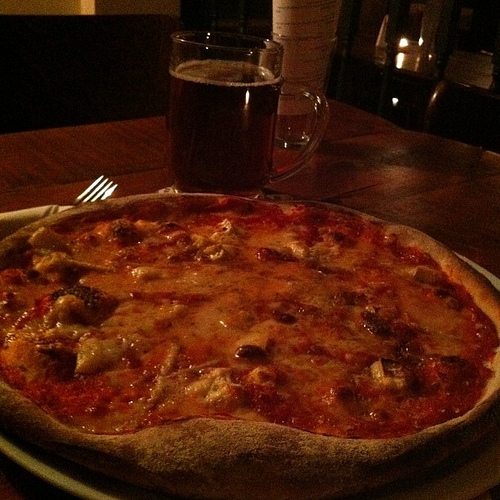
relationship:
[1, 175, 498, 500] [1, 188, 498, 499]
pizza on dish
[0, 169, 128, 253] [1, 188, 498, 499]
fork on dish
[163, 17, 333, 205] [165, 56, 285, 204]
glass of beer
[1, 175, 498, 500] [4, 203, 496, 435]
pizza has sauce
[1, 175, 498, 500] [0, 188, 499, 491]
pizza has crust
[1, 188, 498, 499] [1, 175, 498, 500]
dish under pizza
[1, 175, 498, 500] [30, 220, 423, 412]
pizza has vegetables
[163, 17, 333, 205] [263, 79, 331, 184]
glass has handle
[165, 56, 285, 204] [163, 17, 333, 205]
beer in glass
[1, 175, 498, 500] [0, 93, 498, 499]
pizza on table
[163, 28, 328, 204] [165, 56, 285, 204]
glass of beer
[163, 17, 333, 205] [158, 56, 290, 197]
glass of wine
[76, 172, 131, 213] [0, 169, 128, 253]
top of fork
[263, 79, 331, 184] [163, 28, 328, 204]
handle of glass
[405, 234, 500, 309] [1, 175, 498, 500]
edge of plate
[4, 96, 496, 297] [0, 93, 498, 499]
top of table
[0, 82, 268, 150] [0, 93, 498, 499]
edge of table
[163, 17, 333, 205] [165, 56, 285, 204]
cup of beer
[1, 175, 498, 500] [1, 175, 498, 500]
pizza on plate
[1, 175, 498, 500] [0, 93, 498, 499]
plate on table